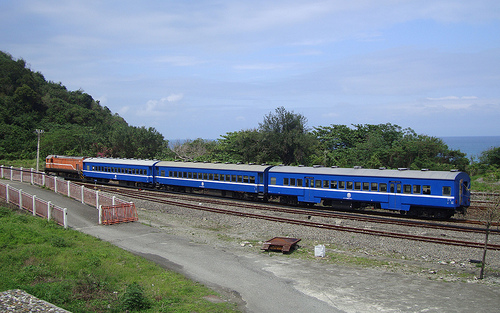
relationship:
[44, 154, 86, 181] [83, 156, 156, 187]
car attached to car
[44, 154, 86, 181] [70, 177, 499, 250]
car on tracks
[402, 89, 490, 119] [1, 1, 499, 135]
clouds in sky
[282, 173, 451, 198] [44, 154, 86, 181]
windows on car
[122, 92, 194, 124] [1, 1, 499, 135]
clouds in sky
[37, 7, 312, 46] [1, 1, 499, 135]
clouds in sky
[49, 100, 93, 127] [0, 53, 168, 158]
bushes on hill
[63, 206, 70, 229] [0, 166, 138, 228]
post on fence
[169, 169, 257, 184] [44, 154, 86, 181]
windows on car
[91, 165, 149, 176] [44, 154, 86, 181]
windows on car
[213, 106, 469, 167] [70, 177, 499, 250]
brush beside tracks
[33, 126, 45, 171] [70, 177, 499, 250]
pole beside tracks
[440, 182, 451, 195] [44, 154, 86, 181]
window on car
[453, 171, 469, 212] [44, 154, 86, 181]
front of car